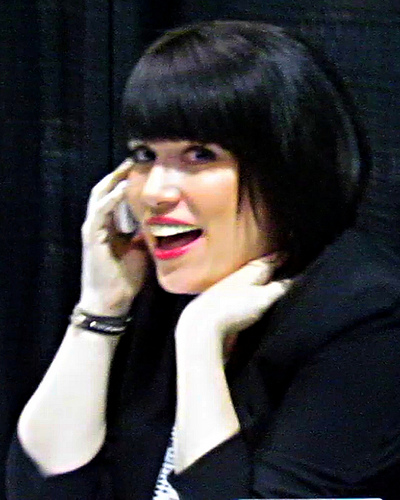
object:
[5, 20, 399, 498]
woman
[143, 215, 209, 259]
smile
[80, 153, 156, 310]
hand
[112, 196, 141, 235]
cellphone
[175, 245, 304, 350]
hand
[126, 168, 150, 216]
cheek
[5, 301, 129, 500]
arms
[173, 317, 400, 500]
arms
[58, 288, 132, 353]
wrist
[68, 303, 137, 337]
bracelet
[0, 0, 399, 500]
background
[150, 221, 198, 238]
teeth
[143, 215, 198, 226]
lipstick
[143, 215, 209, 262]
mouth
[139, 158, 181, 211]
nose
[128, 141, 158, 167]
eyes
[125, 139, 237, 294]
face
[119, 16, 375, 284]
hair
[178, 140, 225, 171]
eyes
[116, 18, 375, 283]
hairstyle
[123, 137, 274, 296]
makeup